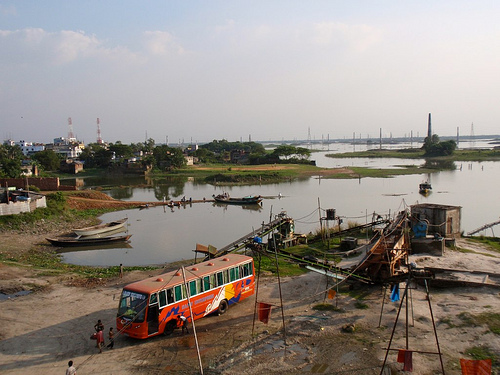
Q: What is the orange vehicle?
A: A bus.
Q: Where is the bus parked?
A: On mud.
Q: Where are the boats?
A: In the water.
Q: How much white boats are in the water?
A: One.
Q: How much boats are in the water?
A: Four.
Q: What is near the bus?
A: Mud puddles.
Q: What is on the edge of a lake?
A: Storage building.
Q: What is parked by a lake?
A: Large orange bus.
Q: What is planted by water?
A: Several green trees.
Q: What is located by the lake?
A: Green grass.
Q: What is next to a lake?
A: Large sandy area.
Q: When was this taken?
A: Day time.